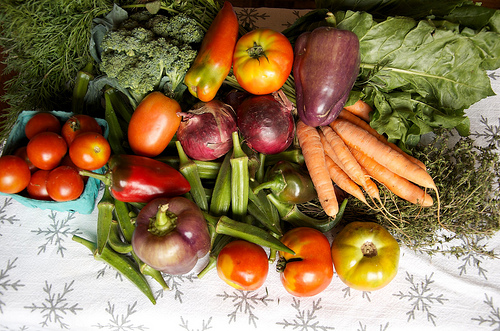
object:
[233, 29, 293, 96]
tomato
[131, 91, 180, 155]
tomato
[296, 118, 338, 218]
carrot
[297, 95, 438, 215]
bundle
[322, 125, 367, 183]
carrot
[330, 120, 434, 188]
carrot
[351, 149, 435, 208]
carrot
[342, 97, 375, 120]
carrot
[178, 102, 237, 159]
onion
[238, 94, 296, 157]
onion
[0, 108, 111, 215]
container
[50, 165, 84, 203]
tomato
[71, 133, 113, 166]
tomato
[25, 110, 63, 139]
tomato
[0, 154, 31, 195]
tomato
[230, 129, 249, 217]
okra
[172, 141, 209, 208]
okra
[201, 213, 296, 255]
okra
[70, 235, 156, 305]
okra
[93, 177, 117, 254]
okra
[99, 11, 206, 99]
broccoli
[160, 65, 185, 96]
stalk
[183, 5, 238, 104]
pepper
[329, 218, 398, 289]
vegetables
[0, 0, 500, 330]
photo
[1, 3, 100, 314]
left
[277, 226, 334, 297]
tomato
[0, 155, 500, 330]
table cloth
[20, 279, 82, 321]
snowflakes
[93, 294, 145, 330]
snowflakes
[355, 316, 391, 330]
snowflakes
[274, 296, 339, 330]
snowflakes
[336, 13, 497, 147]
vegetable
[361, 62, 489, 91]
vein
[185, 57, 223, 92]
spot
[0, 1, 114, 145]
rosemary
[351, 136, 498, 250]
thyme herb